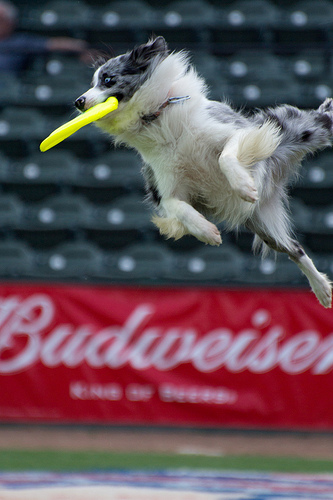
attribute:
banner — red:
[1, 284, 332, 430]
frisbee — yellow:
[37, 95, 118, 152]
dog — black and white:
[68, 52, 323, 285]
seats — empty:
[7, 156, 151, 278]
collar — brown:
[131, 93, 174, 123]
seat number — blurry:
[37, 207, 55, 224]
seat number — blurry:
[184, 254, 206, 274]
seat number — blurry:
[295, 59, 310, 73]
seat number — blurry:
[45, 59, 62, 72]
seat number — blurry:
[259, 252, 278, 274]